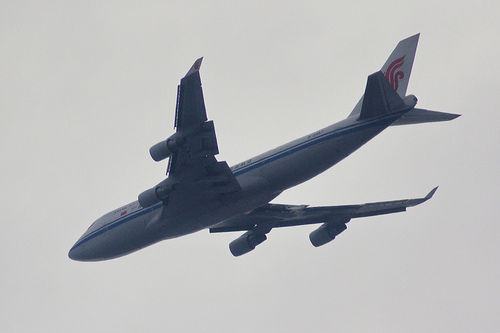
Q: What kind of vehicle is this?
A: A plane.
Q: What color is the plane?
A: White.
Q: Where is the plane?
A: In the sky.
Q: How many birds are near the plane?
A: None.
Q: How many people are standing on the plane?
A: Zero.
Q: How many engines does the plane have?
A: 4.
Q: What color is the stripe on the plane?
A: Blue.